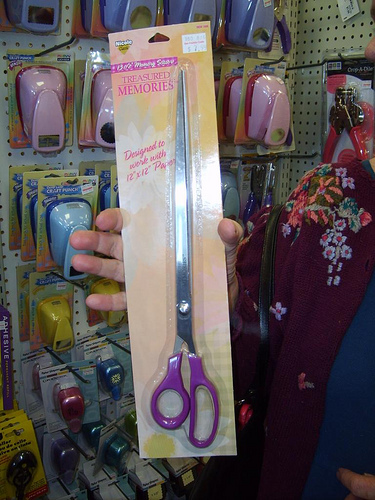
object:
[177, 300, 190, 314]
metal piece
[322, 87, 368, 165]
metal part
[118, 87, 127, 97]
letters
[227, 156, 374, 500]
sweater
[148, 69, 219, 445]
scissors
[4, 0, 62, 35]
objects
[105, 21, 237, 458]
package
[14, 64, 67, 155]
item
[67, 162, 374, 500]
lady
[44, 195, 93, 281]
product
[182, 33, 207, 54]
tag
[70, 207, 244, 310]
hand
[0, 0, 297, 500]
wall